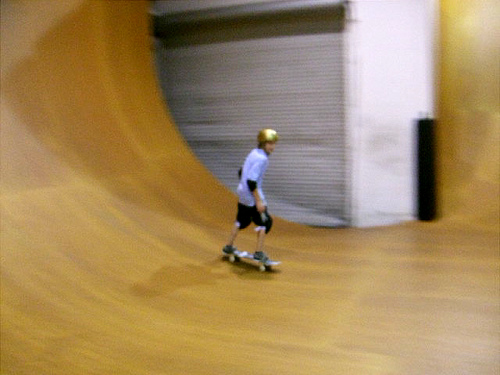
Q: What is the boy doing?
A: Skateboarding.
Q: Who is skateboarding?
A: The boy.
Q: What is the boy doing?
A: Skateboarding.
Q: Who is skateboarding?
A: The boy.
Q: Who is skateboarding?
A: The boy.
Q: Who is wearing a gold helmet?
A: The boy.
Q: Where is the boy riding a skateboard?
A: On a wooden ramp.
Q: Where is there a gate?
A: By ramp.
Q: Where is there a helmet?
A: Skateboarder's head.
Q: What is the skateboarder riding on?
A: A ramp.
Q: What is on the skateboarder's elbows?
A: Pads.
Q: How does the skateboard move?
A: Wheels.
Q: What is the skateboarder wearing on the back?
A: Blue shirt.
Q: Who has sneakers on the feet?
A: Skateboarder.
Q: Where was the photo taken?
A: Skate park.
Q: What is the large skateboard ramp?
A: The ramp is wooden.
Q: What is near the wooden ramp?
A: The wall.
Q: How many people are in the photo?
A: 1.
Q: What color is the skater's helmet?
A: Gold.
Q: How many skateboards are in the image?
A: 1.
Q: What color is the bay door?
A: Gray.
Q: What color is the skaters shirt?
A: Blue.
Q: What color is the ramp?
A: Brown.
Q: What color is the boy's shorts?
A: Black.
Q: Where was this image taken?
A: At the skateboard ramp.